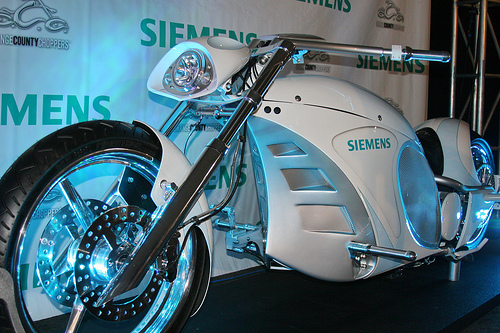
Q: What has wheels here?
A: Motorcycle.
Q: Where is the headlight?
A: On the bike.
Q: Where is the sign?
A: On the wall.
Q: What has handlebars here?
A: The bike.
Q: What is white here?
A: The bike.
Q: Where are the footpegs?
A: On the bike.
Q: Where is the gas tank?
A: On the bike.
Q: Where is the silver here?
A: On the bike.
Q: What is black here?
A: The tires.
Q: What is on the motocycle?
A: Siemens sign.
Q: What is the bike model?
A: Siemens.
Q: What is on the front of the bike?
A: Headlights.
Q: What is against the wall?
A: White bike.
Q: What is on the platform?
A: Motorcycle.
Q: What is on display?
A: Siemens bike.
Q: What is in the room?
A: Motorcycle.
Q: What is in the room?
A: New motorcycle.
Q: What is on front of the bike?
A: Headlight.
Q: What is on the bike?
A: Footrest.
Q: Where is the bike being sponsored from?
A: Siemens.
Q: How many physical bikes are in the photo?
A: 1.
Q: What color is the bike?
A: White.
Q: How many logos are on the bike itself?
A: 1.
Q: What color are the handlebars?
A: Chrome.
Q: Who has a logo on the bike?
A: Siemens.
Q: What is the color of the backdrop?
A: White.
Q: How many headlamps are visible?
A: 1.